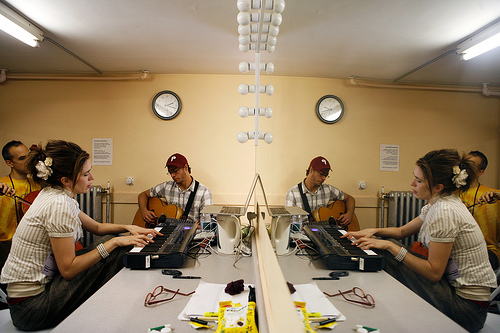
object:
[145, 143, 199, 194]
man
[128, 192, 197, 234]
guitar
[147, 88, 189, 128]
clock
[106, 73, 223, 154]
wall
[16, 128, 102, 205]
lady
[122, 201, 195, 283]
keyboard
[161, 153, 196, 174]
cap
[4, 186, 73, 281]
blouse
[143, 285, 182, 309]
eyeglasses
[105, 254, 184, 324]
counter